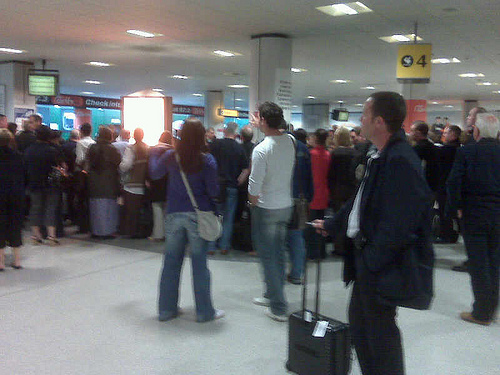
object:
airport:
[0, 0, 500, 375]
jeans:
[157, 211, 214, 324]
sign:
[121, 95, 172, 146]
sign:
[396, 41, 431, 80]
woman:
[148, 118, 225, 323]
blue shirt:
[149, 146, 221, 212]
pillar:
[247, 35, 292, 141]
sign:
[219, 109, 239, 116]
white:
[0, 242, 498, 374]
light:
[313, 0, 372, 17]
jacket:
[325, 127, 436, 310]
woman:
[85, 124, 123, 239]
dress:
[85, 142, 123, 237]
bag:
[172, 147, 223, 242]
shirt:
[248, 132, 303, 209]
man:
[446, 112, 499, 325]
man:
[205, 122, 249, 257]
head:
[473, 112, 498, 141]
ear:
[375, 116, 384, 130]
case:
[285, 222, 350, 374]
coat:
[80, 143, 120, 199]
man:
[246, 102, 295, 322]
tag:
[312, 321, 330, 338]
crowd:
[0, 91, 496, 375]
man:
[310, 91, 436, 375]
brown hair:
[368, 91, 407, 132]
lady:
[309, 128, 330, 257]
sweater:
[309, 146, 330, 210]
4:
[417, 54, 427, 67]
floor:
[0, 242, 500, 375]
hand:
[313, 219, 328, 237]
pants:
[1, 186, 23, 249]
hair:
[178, 120, 205, 173]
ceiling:
[0, 0, 500, 108]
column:
[277, 69, 291, 111]